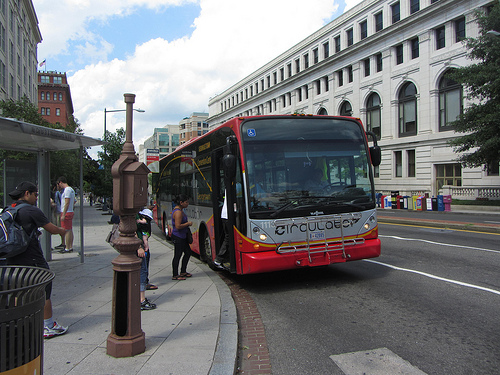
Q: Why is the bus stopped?
A: To let people on.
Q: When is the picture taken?
A: Daytime.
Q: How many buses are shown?
A: 1.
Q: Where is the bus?
A: At the curb.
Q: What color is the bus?
A: Gray and red.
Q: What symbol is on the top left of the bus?
A: A handicap sign.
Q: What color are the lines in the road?
A: White.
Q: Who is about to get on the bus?
A: A woman.